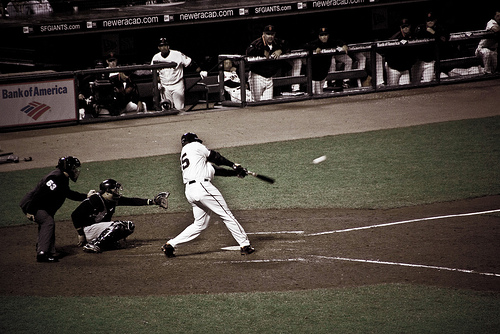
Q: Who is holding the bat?
A: A baseball player.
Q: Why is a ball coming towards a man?
A: He is playing a game of baseball.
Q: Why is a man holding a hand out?
A: He is trying to catch a ball.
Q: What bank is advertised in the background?
A: Bank of America.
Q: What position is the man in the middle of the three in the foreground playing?
A: Catcher.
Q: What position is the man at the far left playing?
A: Umpire.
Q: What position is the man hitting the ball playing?
A: Batter.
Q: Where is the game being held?
A: On a baseball field.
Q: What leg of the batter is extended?
A: Right.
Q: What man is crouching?
A: Catcher.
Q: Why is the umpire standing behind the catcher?
A: To officiate the game.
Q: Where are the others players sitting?
A: In the dugout.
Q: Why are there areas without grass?
A: Pathway for the players to run bases.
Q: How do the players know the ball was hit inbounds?
A: The white lines on the field.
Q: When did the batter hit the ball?
A: A few seconds before the scene was captured.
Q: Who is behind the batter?
A: The catcher for the other team.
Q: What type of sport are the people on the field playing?
A: Professional baseball.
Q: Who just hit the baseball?
A: The batter.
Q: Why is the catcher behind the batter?
A: To catch the pitch.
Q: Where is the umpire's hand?
A: On the catcher's shoulder.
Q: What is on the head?
A: Helmet.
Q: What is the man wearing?
A: Man wearing a white uniform.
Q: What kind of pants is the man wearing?
A: Man wearing uniform pants.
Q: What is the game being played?
A: Baseball.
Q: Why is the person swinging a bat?
A: He is hitting a baseball.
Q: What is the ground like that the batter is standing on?
A: Dirt.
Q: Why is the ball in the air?
A: It was hit.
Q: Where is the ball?
A: In the air.